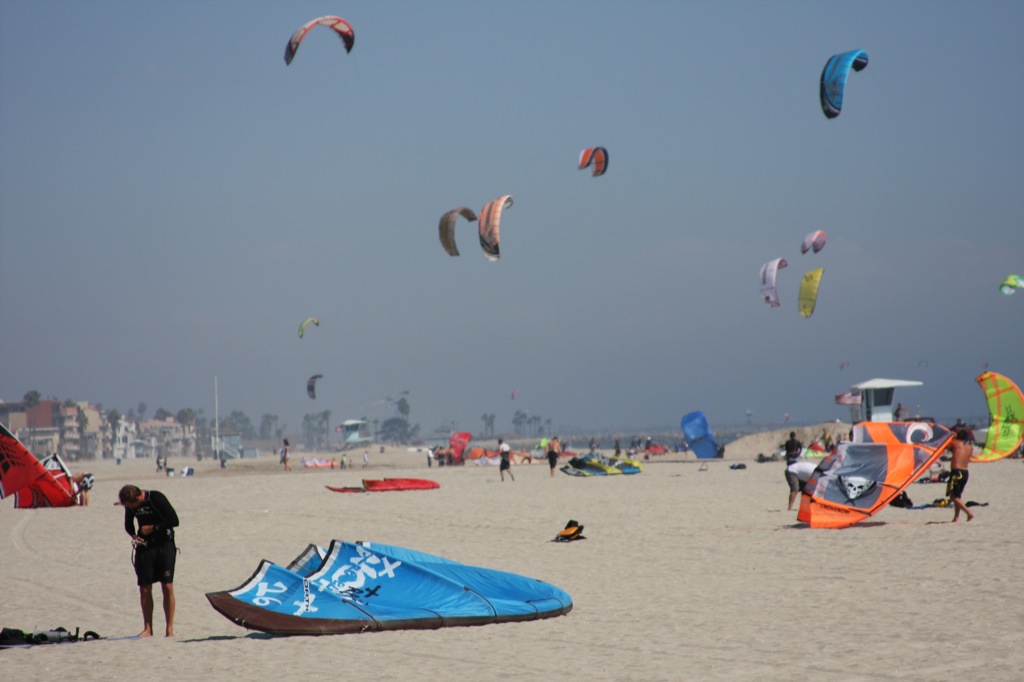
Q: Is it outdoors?
A: Yes, it is outdoors.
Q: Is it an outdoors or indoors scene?
A: It is outdoors.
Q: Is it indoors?
A: No, it is outdoors.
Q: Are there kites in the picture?
A: Yes, there is a kite.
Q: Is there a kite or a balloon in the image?
A: Yes, there is a kite.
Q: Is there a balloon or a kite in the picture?
A: Yes, there is a kite.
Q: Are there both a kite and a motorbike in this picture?
A: No, there is a kite but no motorcycles.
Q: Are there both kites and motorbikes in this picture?
A: No, there is a kite but no motorcycles.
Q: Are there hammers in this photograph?
A: No, there are no hammers.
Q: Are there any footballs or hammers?
A: No, there are no hammers or footballs.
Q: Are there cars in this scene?
A: No, there are no cars.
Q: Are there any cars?
A: No, there are no cars.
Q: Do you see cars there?
A: No, there are no cars.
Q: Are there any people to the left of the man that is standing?
A: Yes, there are people to the left of the man.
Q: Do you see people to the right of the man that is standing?
A: No, the people are to the left of the man.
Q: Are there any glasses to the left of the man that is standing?
A: No, there are people to the left of the man.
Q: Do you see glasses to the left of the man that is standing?
A: No, there are people to the left of the man.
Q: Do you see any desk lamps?
A: No, there are no desk lamps.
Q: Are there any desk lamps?
A: No, there are no desk lamps.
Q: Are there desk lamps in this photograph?
A: No, there are no desk lamps.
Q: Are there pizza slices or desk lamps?
A: No, there are no desk lamps or pizza slices.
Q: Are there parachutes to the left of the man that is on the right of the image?
A: Yes, there is a parachute to the left of the man.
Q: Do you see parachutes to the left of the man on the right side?
A: Yes, there is a parachute to the left of the man.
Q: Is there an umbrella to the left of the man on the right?
A: No, there is a parachute to the left of the man.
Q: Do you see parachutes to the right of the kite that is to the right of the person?
A: Yes, there is a parachute to the right of the kite.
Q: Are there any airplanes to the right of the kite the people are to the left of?
A: No, there is a parachute to the right of the kite.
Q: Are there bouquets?
A: No, there are no bouquets.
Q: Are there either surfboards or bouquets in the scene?
A: No, there are no bouquets or surfboards.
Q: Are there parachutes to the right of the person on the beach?
A: Yes, there is a parachute to the right of the person.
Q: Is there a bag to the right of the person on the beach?
A: No, there is a parachute to the right of the person.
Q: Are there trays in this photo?
A: No, there are no trays.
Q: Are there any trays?
A: No, there are no trays.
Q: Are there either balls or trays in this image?
A: No, there are no trays or balls.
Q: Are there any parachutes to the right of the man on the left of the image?
A: Yes, there is a parachute to the right of the man.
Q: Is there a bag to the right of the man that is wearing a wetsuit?
A: No, there is a parachute to the right of the man.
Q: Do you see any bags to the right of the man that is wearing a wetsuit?
A: No, there is a parachute to the right of the man.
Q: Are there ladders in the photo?
A: No, there are no ladders.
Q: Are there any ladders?
A: No, there are no ladders.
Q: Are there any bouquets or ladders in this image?
A: No, there are no ladders or bouquets.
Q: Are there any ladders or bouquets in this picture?
A: No, there are no ladders or bouquets.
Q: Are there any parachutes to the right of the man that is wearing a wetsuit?
A: Yes, there is a parachute to the right of the man.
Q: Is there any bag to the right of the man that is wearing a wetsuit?
A: No, there is a parachute to the right of the man.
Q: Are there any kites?
A: Yes, there is a kite.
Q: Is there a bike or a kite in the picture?
A: Yes, there is a kite.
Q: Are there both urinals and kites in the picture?
A: No, there is a kite but no urinals.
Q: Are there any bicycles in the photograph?
A: No, there are no bicycles.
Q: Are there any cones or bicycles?
A: No, there are no bicycles or cones.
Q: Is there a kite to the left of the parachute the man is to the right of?
A: Yes, there is a kite to the left of the parachute.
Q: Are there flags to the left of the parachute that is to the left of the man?
A: No, there is a kite to the left of the parachute.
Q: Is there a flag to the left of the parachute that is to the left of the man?
A: No, there is a kite to the left of the parachute.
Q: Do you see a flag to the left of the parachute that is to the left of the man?
A: No, there is a kite to the left of the parachute.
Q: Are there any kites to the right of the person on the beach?
A: Yes, there is a kite to the right of the person.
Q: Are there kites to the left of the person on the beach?
A: No, the kite is to the right of the person.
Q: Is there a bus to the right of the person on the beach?
A: No, there is a kite to the right of the person.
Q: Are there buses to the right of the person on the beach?
A: No, there is a kite to the right of the person.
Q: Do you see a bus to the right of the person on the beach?
A: No, there is a kite to the right of the person.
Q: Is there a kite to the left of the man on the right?
A: Yes, there is a kite to the left of the man.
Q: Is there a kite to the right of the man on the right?
A: No, the kite is to the left of the man.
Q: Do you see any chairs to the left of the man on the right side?
A: No, there is a kite to the left of the man.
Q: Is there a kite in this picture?
A: Yes, there is a kite.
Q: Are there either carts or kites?
A: Yes, there is a kite.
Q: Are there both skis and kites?
A: No, there is a kite but no skis.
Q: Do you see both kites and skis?
A: No, there is a kite but no skis.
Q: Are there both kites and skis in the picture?
A: No, there is a kite but no skis.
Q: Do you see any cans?
A: No, there are no cans.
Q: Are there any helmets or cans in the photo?
A: No, there are no cans or helmets.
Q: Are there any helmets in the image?
A: No, there are no helmets.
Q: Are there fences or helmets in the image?
A: No, there are no helmets or fences.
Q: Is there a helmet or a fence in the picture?
A: No, there are no helmets or fences.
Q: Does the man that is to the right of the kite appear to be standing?
A: Yes, the man is standing.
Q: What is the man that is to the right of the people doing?
A: The man is standing.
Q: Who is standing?
A: The man is standing.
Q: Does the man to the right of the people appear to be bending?
A: No, the man is standing.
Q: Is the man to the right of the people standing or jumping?
A: The man is standing.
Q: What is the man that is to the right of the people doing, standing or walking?
A: The man is standing.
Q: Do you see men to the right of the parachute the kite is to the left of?
A: Yes, there is a man to the right of the parachute.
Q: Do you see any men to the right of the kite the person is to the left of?
A: Yes, there is a man to the right of the kite.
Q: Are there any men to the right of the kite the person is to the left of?
A: Yes, there is a man to the right of the kite.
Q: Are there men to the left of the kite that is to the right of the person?
A: No, the man is to the right of the kite.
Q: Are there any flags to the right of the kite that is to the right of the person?
A: No, there is a man to the right of the kite.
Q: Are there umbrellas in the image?
A: No, there are no umbrellas.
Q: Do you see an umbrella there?
A: No, there are no umbrellas.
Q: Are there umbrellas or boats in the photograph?
A: No, there are no umbrellas or boats.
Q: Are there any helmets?
A: No, there are no helmets.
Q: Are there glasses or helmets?
A: No, there are no helmets or glasses.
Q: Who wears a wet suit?
A: The man wears a wet suit.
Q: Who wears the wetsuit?
A: The man wears a wet suit.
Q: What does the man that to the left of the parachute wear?
A: The man wears a wetsuit.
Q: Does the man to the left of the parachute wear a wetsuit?
A: Yes, the man wears a wetsuit.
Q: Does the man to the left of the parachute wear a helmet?
A: No, the man wears a wetsuit.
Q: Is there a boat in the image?
A: No, there are no boats.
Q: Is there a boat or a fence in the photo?
A: No, there are no boats or fences.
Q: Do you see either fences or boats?
A: No, there are no boats or fences.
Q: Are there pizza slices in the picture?
A: No, there are no pizza slices.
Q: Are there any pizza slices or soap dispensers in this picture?
A: No, there are no pizza slices or soap dispensers.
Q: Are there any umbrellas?
A: No, there are no umbrellas.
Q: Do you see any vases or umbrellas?
A: No, there are no umbrellas or vases.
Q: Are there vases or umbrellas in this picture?
A: No, there are no umbrellas or vases.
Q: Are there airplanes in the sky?
A: No, there are parachutes in the sky.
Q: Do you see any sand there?
A: Yes, there is sand.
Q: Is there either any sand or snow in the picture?
A: Yes, there is sand.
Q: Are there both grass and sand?
A: No, there is sand but no grass.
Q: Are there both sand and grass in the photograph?
A: No, there is sand but no grass.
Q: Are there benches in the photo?
A: No, there are no benches.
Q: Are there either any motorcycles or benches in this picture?
A: No, there are no benches or motorcycles.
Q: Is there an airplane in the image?
A: No, there are no airplanes.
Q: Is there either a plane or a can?
A: No, there are no airplanes or cans.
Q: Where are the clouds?
A: The clouds are in the sky.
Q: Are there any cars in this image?
A: No, there are no cars.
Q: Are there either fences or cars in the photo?
A: No, there are no cars or fences.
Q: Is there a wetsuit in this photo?
A: Yes, there is a wetsuit.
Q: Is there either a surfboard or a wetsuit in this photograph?
A: Yes, there is a wetsuit.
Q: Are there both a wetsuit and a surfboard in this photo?
A: No, there is a wetsuit but no surfboards.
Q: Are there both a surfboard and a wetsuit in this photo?
A: No, there is a wetsuit but no surfboards.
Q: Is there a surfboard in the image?
A: No, there are no surfboards.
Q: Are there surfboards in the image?
A: No, there are no surfboards.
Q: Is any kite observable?
A: Yes, there is a kite.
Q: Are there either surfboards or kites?
A: Yes, there is a kite.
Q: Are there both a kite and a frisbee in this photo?
A: No, there is a kite but no frisbees.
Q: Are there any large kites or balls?
A: Yes, there is a large kite.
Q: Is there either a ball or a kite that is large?
A: Yes, the kite is large.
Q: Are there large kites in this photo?
A: Yes, there is a large kite.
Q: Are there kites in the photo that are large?
A: Yes, there is a large kite.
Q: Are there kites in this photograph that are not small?
A: Yes, there is a large kite.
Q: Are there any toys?
A: No, there are no toys.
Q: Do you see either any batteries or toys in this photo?
A: No, there are no toys or batteries.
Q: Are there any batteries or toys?
A: No, there are no toys or batteries.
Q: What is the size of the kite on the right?
A: The kite is large.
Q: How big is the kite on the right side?
A: The kite is large.